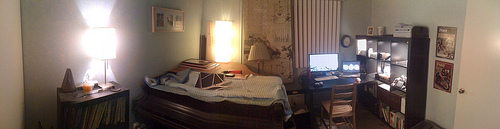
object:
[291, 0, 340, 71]
wall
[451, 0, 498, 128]
door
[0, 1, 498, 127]
room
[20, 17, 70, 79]
wall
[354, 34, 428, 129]
bookshelf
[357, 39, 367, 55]
light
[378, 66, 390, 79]
light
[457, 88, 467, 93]
handle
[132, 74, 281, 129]
bed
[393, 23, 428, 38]
white printer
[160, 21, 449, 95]
home office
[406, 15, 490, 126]
wall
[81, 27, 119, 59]
light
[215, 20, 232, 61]
wall lights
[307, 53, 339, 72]
computer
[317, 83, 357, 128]
chair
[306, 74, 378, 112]
desk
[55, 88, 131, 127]
bookcase